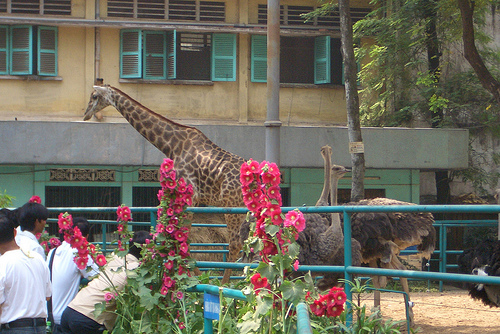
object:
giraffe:
[82, 85, 279, 288]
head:
[82, 77, 113, 129]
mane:
[103, 78, 190, 145]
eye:
[89, 92, 98, 99]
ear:
[92, 77, 109, 95]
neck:
[112, 93, 183, 147]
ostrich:
[312, 142, 433, 326]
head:
[317, 140, 336, 161]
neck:
[317, 155, 334, 202]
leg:
[400, 270, 418, 319]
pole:
[262, 0, 286, 166]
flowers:
[241, 174, 254, 186]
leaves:
[300, 2, 497, 127]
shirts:
[43, 241, 103, 326]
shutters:
[248, 27, 332, 86]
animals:
[80, 57, 499, 297]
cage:
[9, 205, 500, 333]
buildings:
[0, 0, 500, 272]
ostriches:
[271, 161, 363, 290]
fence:
[0, 205, 500, 218]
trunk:
[343, 2, 372, 194]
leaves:
[253, 258, 284, 285]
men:
[0, 207, 55, 333]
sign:
[202, 295, 220, 318]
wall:
[0, 81, 354, 123]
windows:
[164, 26, 238, 83]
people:
[62, 229, 151, 333]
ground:
[349, 283, 500, 330]